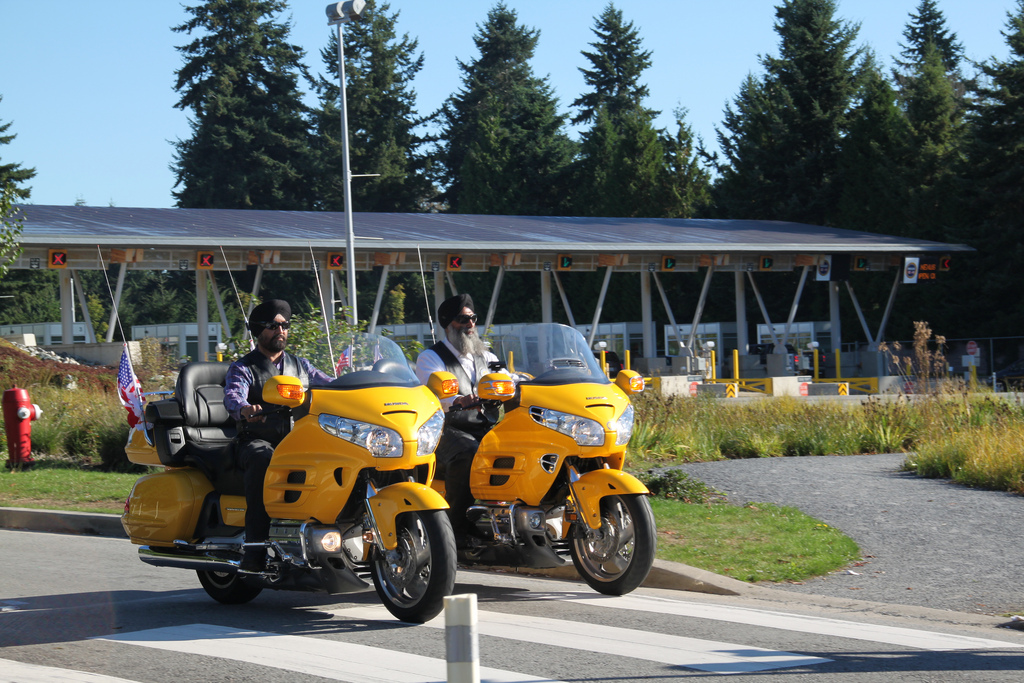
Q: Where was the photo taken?
A: Near a checkpoint.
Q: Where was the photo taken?
A: Pay road.